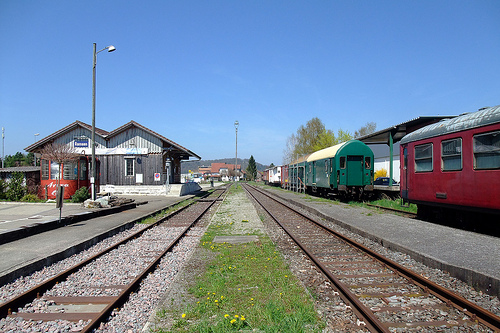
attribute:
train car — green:
[287, 141, 387, 206]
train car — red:
[393, 106, 498, 227]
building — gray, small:
[30, 117, 202, 179]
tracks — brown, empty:
[26, 181, 476, 328]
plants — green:
[165, 225, 302, 330]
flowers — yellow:
[223, 312, 250, 327]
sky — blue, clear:
[2, 1, 493, 145]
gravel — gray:
[90, 258, 140, 278]